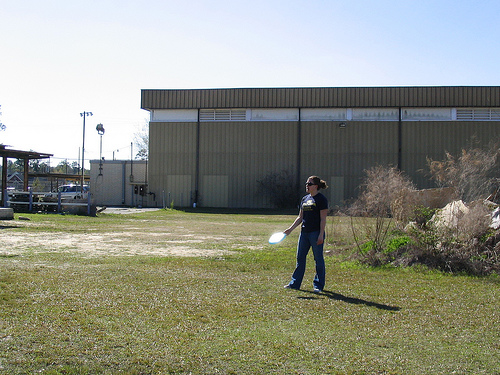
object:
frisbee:
[267, 230, 285, 244]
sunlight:
[267, 230, 284, 243]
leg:
[309, 237, 325, 287]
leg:
[289, 242, 310, 287]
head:
[303, 174, 322, 195]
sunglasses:
[304, 180, 315, 186]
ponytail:
[320, 179, 329, 191]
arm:
[287, 197, 305, 233]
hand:
[282, 228, 292, 236]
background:
[0, 0, 500, 373]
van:
[41, 183, 90, 200]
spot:
[80, 227, 99, 232]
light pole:
[80, 112, 87, 200]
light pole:
[97, 134, 104, 157]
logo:
[301, 199, 315, 207]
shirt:
[298, 191, 330, 233]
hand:
[316, 231, 325, 247]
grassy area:
[0, 208, 500, 373]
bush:
[324, 142, 499, 278]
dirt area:
[0, 219, 270, 259]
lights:
[88, 110, 96, 115]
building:
[140, 85, 499, 212]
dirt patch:
[0, 220, 266, 258]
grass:
[0, 205, 498, 375]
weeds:
[326, 134, 500, 275]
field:
[0, 208, 500, 373]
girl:
[280, 174, 331, 296]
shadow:
[297, 283, 401, 314]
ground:
[0, 206, 500, 374]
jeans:
[287, 229, 326, 289]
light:
[79, 110, 86, 118]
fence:
[7, 192, 97, 215]